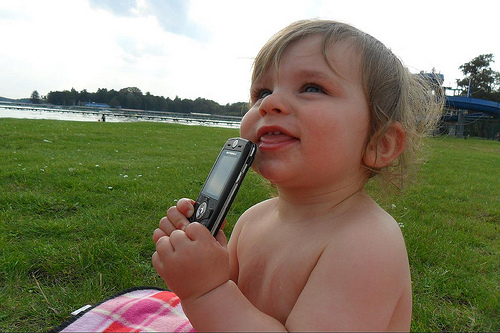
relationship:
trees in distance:
[41, 82, 206, 106] [0, 70, 239, 119]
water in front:
[1, 104, 170, 123] [0, 98, 226, 122]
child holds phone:
[123, 8, 419, 332] [167, 111, 272, 260]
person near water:
[85, 101, 118, 136] [1, 104, 170, 123]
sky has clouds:
[8, 24, 221, 88] [24, 6, 219, 69]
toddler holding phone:
[123, 8, 419, 332] [167, 111, 272, 260]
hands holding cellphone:
[127, 196, 253, 284] [167, 111, 272, 260]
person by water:
[85, 101, 118, 136] [1, 104, 170, 123]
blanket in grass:
[35, 276, 187, 329] [8, 135, 146, 279]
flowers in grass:
[32, 133, 165, 213] [8, 135, 146, 279]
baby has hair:
[123, 8, 419, 332] [244, 12, 440, 80]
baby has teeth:
[123, 8, 419, 332] [267, 123, 294, 139]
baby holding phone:
[123, 8, 419, 332] [167, 111, 272, 260]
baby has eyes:
[123, 8, 419, 332] [227, 51, 348, 95]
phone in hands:
[167, 111, 272, 260] [127, 196, 253, 284]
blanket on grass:
[35, 276, 187, 329] [8, 135, 146, 279]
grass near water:
[8, 135, 146, 279] [1, 104, 170, 123]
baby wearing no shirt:
[123, 8, 419, 332] [187, 209, 415, 315]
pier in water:
[0, 98, 226, 122] [1, 104, 170, 123]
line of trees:
[9, 89, 244, 117] [41, 82, 206, 106]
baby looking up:
[123, 8, 419, 332] [242, 50, 381, 172]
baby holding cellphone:
[123, 8, 419, 332] [167, 111, 272, 260]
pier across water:
[0, 98, 226, 122] [1, 104, 170, 123]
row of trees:
[9, 89, 244, 117] [41, 82, 206, 106]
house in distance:
[76, 95, 116, 115] [0, 70, 239, 119]